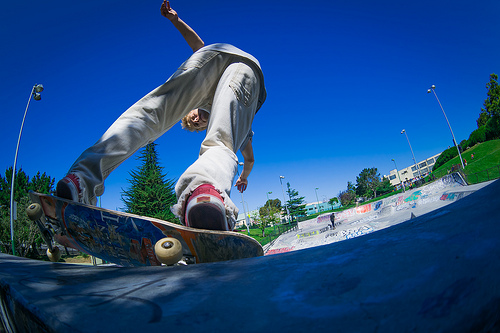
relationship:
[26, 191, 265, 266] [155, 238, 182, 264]
skateboard has a wheel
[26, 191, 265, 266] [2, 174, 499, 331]
skateboard in a skatepark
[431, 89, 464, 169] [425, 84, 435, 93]
pole has a lamp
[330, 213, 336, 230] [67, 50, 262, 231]
person wearing jeans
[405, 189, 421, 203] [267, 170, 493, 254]
graffiti on ground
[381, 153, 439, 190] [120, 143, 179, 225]
building near a tree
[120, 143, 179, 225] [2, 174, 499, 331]
tree past skatepark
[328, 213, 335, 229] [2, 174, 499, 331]
person in skatepark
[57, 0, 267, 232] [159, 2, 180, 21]
guy has a hand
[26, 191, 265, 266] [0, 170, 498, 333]
skateboard on a ramp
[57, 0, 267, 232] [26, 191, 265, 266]
guy on a skateboard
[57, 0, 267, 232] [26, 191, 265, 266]
guy has a skateboard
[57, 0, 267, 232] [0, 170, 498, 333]
guy on a ramp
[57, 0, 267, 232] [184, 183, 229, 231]
guy has on shoe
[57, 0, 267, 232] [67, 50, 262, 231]
guy has on jeans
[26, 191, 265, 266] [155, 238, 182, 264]
skateboard has wheel